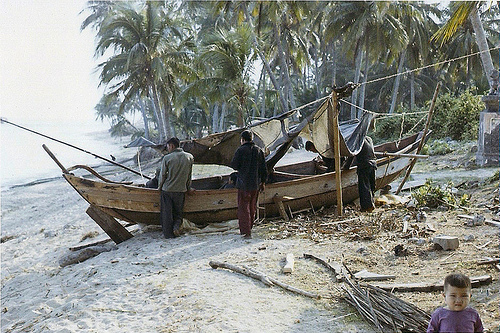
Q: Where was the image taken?
A: It was taken at the beach.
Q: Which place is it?
A: It is a beach.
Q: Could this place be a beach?
A: Yes, it is a beach.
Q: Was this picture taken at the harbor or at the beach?
A: It was taken at the beach.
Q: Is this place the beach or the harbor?
A: It is the beach.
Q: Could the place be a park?
A: No, it is a beach.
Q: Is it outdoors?
A: Yes, it is outdoors.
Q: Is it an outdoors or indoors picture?
A: It is outdoors.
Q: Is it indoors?
A: No, it is outdoors.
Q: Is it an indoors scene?
A: No, it is outdoors.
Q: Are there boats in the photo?
A: Yes, there is a boat.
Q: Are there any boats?
A: Yes, there is a boat.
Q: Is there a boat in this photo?
A: Yes, there is a boat.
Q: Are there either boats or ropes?
A: Yes, there is a boat.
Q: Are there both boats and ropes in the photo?
A: Yes, there are both a boat and a rope.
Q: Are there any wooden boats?
A: Yes, there is a wood boat.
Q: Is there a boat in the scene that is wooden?
A: Yes, there is a boat that is wooden.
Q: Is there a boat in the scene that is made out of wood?
A: Yes, there is a boat that is made of wood.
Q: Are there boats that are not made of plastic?
A: Yes, there is a boat that is made of wood.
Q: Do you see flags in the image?
A: No, there are no flags.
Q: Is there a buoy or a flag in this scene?
A: No, there are no flags or buoys.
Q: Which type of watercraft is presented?
A: The watercraft is a boat.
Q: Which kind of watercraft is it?
A: The watercraft is a boat.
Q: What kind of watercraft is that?
A: This is a boat.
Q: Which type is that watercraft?
A: This is a boat.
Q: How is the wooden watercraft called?
A: The watercraft is a boat.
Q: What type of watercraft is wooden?
A: The watercraft is a boat.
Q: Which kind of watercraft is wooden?
A: The watercraft is a boat.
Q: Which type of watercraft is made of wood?
A: The watercraft is a boat.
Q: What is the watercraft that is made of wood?
A: The watercraft is a boat.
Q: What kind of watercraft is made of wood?
A: The watercraft is a boat.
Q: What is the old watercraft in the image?
A: The watercraft is a boat.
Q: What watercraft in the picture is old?
A: The watercraft is a boat.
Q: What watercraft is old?
A: The watercraft is a boat.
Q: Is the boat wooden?
A: Yes, the boat is wooden.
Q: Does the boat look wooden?
A: Yes, the boat is wooden.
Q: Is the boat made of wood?
A: Yes, the boat is made of wood.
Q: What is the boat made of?
A: The boat is made of wood.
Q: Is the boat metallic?
A: No, the boat is wooden.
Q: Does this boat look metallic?
A: No, the boat is wooden.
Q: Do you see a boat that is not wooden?
A: No, there is a boat but it is wooden.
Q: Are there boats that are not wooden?
A: No, there is a boat but it is wooden.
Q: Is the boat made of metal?
A: No, the boat is made of wood.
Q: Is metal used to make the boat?
A: No, the boat is made of wood.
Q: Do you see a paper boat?
A: No, there is a boat but it is made of wood.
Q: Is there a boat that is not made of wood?
A: No, there is a boat but it is made of wood.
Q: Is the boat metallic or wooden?
A: The boat is wooden.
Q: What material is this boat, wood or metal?
A: The boat is made of wood.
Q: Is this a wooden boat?
A: Yes, this is a wooden boat.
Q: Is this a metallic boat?
A: No, this is a wooden boat.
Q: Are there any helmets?
A: No, there are no helmets.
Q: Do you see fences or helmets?
A: No, there are no helmets or fences.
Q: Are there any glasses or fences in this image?
A: No, there are no fences or glasses.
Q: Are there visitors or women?
A: No, there are no visitors or women.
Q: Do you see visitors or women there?
A: No, there are no visitors or women.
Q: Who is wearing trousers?
A: The man is wearing trousers.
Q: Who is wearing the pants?
A: The man is wearing trousers.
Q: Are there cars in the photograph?
A: No, there are no cars.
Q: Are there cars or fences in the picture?
A: No, there are no cars or fences.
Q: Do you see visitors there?
A: No, there are no visitors.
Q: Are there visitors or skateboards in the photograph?
A: No, there are no visitors or skateboards.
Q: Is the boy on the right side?
A: Yes, the boy is on the right of the image.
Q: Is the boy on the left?
A: No, the boy is on the right of the image.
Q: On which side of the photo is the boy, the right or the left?
A: The boy is on the right of the image.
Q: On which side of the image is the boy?
A: The boy is on the right of the image.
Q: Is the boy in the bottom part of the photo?
A: Yes, the boy is in the bottom of the image.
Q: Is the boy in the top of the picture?
A: No, the boy is in the bottom of the image.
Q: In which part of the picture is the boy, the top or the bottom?
A: The boy is in the bottom of the image.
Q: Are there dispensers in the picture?
A: No, there are no dispensers.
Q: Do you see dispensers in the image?
A: No, there are no dispensers.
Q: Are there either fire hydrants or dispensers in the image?
A: No, there are no dispensers or fire hydrants.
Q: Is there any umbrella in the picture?
A: No, there are no umbrellas.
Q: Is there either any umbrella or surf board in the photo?
A: No, there are no umbrellas or surfboards.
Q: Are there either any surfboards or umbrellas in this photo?
A: No, there are no umbrellas or surfboards.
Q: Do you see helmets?
A: No, there are no helmets.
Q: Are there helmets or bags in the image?
A: No, there are no helmets or bags.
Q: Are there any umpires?
A: No, there are no umpires.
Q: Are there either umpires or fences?
A: No, there are no umpires or fences.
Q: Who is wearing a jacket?
A: The man is wearing a jacket.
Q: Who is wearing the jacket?
A: The man is wearing a jacket.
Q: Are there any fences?
A: No, there are no fences.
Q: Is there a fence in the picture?
A: No, there are no fences.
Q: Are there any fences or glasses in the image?
A: No, there are no fences or glasses.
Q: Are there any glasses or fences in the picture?
A: No, there are no fences or glasses.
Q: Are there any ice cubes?
A: No, there are no ice cubes.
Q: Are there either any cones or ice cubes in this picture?
A: No, there are no ice cubes or cones.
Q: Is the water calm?
A: Yes, the water is calm.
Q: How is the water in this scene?
A: The water is calm.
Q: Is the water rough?
A: No, the water is calm.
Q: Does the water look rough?
A: No, the water is calm.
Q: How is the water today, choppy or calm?
A: The water is calm.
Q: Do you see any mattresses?
A: No, there are no mattresses.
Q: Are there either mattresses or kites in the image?
A: No, there are no mattresses or kites.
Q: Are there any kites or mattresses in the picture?
A: No, there are no mattresses or kites.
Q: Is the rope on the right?
A: Yes, the rope is on the right of the image.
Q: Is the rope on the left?
A: No, the rope is on the right of the image.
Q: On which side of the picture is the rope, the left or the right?
A: The rope is on the right of the image.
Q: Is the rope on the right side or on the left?
A: The rope is on the right of the image.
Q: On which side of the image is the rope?
A: The rope is on the right of the image.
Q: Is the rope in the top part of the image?
A: Yes, the rope is in the top of the image.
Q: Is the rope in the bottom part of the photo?
A: No, the rope is in the top of the image.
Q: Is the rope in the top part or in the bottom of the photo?
A: The rope is in the top of the image.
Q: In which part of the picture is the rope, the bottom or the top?
A: The rope is in the top of the image.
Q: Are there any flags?
A: No, there are no flags.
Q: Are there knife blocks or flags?
A: No, there are no flags or knife blocks.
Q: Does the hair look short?
A: Yes, the hair is short.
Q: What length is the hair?
A: The hair is short.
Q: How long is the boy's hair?
A: The hair is short.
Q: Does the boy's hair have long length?
A: No, the hair is short.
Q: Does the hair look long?
A: No, the hair is short.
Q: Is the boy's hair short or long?
A: The hair is short.